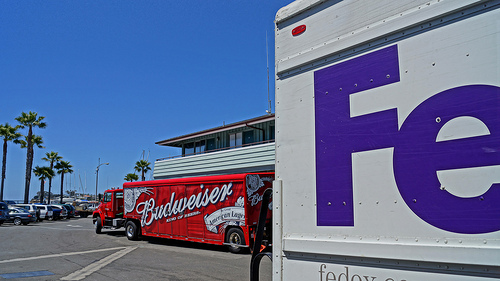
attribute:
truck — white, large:
[273, 1, 498, 279]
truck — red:
[120, 157, 340, 261]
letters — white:
[135, 177, 302, 217]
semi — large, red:
[88, 170, 277, 252]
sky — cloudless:
[4, 0, 293, 221]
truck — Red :
[90, 175, 273, 248]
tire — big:
[125, 219, 138, 241]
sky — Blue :
[1, 0, 273, 195]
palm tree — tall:
[20, 106, 45, 208]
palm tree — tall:
[33, 165, 56, 200]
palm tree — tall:
[2, 123, 27, 198]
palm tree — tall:
[58, 157, 73, 197]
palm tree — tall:
[44, 146, 61, 206]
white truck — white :
[270, 0, 498, 280]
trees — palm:
[16, 102, 105, 216]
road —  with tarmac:
[3, 213, 273, 279]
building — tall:
[152, 109, 274, 172]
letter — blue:
[313, 35, 403, 226]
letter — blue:
[391, 82, 499, 235]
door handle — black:
[243, 186, 275, 279]